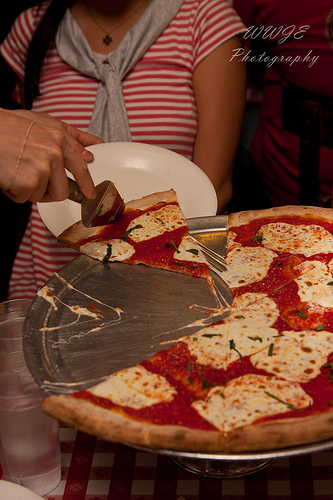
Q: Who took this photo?
A: WWGE Photograph.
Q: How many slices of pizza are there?
A: Five.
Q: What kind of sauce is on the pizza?
A: Tomato Sauce.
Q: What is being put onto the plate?
A: A slice of pizza.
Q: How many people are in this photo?
A: Two.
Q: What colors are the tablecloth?
A: Red and white.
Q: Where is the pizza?
A: On the table.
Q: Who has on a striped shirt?
A: The woman.